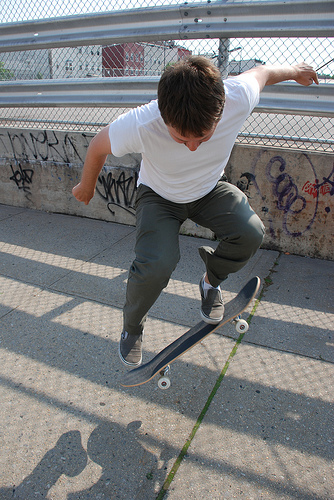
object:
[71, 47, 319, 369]
boy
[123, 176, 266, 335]
pants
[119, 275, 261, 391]
skateboard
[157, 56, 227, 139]
hair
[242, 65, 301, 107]
left arm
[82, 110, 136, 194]
right arm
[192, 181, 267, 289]
left leg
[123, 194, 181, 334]
right leg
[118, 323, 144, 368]
shoes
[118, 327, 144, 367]
right foot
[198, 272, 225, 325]
left foot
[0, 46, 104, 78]
building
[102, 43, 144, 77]
building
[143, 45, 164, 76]
building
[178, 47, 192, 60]
building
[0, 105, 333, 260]
wall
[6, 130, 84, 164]
graffiti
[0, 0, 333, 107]
railing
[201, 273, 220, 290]
sock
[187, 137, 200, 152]
nose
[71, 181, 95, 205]
right hand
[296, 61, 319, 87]
left hand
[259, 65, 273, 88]
elbow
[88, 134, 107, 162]
elbow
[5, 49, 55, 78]
wall